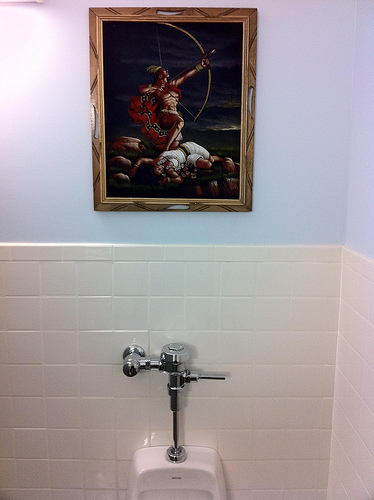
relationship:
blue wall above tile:
[4, 3, 92, 231] [5, 250, 105, 442]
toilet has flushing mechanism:
[116, 345, 230, 498] [181, 372, 225, 386]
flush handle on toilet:
[201, 373, 226, 382] [116, 345, 230, 498]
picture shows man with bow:
[87, 7, 253, 210] [132, 25, 217, 144]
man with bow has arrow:
[132, 25, 217, 144] [170, 51, 216, 84]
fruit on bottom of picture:
[193, 179, 233, 197] [87, 7, 253, 210]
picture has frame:
[87, 7, 253, 210] [91, 8, 107, 213]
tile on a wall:
[111, 265, 145, 299] [4, 247, 373, 361]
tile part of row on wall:
[6, 265, 40, 300] [4, 247, 373, 361]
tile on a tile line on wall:
[111, 265, 145, 299] [4, 247, 373, 361]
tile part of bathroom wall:
[111, 265, 145, 299] [4, 247, 373, 361]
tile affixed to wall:
[111, 265, 145, 299] [4, 247, 373, 361]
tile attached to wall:
[111, 265, 145, 299] [4, 247, 373, 361]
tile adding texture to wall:
[111, 265, 145, 299] [4, 247, 373, 361]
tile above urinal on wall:
[111, 265, 145, 299] [4, 247, 373, 361]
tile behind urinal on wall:
[111, 265, 145, 299] [4, 247, 373, 361]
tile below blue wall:
[111, 265, 145, 299] [260, 16, 363, 229]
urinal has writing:
[116, 345, 230, 498] [170, 474, 184, 482]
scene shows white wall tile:
[1, 1, 370, 498] [6, 265, 40, 300]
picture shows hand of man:
[87, 7, 253, 210] [197, 51, 218, 69]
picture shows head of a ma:
[87, 7, 253, 210] [149, 64, 171, 87]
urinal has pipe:
[116, 345, 230, 498] [120, 347, 145, 376]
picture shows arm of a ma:
[87, 7, 253, 210] [173, 68, 213, 83]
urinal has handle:
[116, 345, 230, 498] [181, 372, 225, 386]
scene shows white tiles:
[1, 1, 370, 498] [6, 297, 116, 499]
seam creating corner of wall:
[324, 0, 342, 497] [260, 16, 363, 229]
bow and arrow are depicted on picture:
[153, 25, 218, 117] [87, 7, 253, 210]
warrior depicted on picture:
[132, 25, 217, 144] [87, 7, 253, 210]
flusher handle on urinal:
[181, 372, 225, 386] [116, 345, 230, 498]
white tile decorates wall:
[81, 295, 115, 335] [4, 247, 373, 361]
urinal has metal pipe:
[116, 345, 230, 498] [120, 347, 145, 376]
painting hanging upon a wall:
[87, 7, 253, 210] [260, 16, 363, 229]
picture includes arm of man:
[87, 7, 253, 210] [137, 63, 210, 146]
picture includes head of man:
[87, 7, 253, 210] [137, 63, 210, 146]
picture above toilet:
[87, 7, 253, 210] [116, 345, 230, 498]